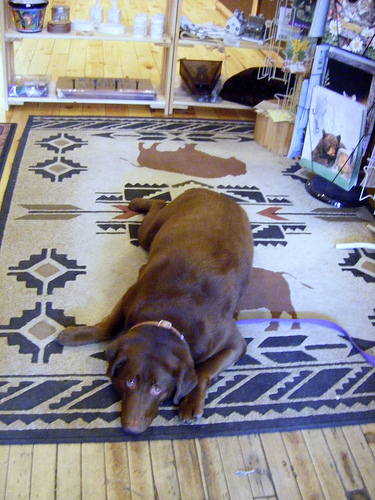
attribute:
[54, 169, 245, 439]
dog — brown, laying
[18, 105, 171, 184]
carpet — blue, white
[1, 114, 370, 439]
rug —  brown , buffalo 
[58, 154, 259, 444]
dog — brown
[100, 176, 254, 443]
dog —  brown 